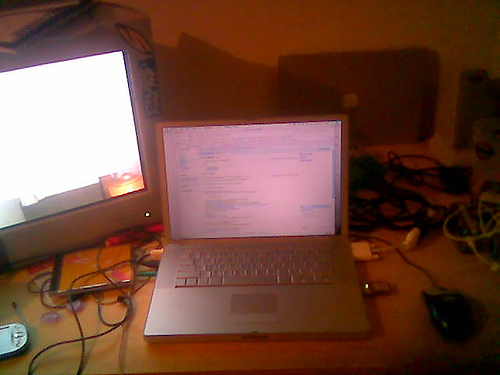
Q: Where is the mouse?
A: Right of the laptop.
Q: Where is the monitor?
A: Left of the laptop.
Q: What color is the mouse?
A: Black.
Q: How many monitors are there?
A: 2.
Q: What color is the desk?
A: Brown.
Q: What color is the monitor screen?
A: White.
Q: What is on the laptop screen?
A: Words.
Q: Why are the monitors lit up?
A: On.